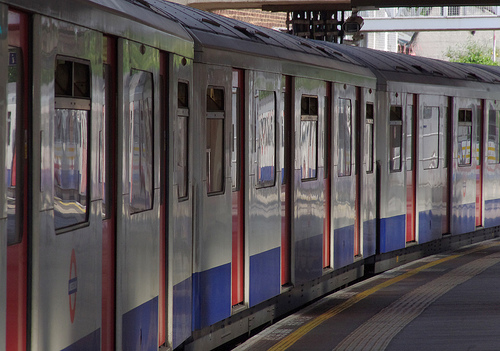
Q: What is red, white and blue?
A: A train.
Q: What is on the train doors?
A: Stripes.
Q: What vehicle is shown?
A: Train.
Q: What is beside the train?
A: A walkway.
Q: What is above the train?
A: Supports.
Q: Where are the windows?
A: On the train.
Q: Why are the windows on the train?
A: To see out of.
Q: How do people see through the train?
A: Windows.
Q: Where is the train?
A: On the tracks.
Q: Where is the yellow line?
A: Beside the train.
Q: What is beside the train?
A: A yellow line.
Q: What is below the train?
A: Tracks.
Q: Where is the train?
A: Station.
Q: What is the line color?
A: Yellow.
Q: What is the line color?
A: Yellow.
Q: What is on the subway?
A: Door.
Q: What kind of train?
A: Passenger.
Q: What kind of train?
A: Passenger.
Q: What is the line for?
A: Boundary.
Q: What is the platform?
A: Curved.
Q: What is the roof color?
A: Black.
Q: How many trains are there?
A: One.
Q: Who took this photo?
A: A professional photographer.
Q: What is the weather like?
A: Sunny.